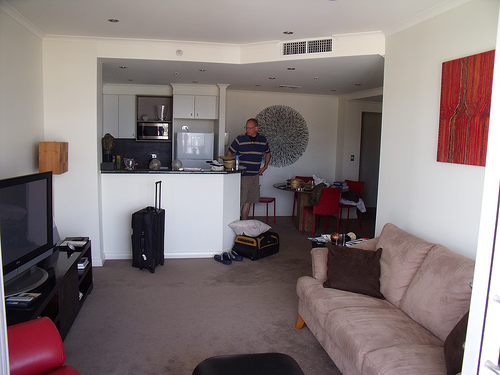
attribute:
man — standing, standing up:
[227, 119, 273, 222]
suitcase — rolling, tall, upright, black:
[132, 182, 166, 272]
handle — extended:
[152, 180, 162, 211]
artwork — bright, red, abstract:
[435, 50, 492, 166]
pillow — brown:
[324, 245, 385, 300]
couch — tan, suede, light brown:
[296, 223, 474, 374]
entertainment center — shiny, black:
[5, 245, 91, 339]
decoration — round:
[253, 104, 309, 169]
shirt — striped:
[231, 134, 271, 176]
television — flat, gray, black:
[1, 170, 54, 279]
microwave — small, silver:
[138, 125, 171, 142]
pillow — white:
[228, 220, 273, 237]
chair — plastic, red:
[301, 187, 341, 235]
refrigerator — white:
[174, 131, 213, 169]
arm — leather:
[8, 317, 66, 373]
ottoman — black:
[199, 352, 304, 374]